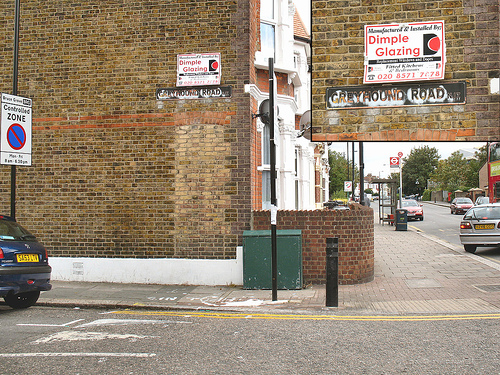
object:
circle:
[7, 124, 26, 151]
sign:
[176, 52, 223, 87]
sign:
[362, 21, 443, 83]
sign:
[325, 82, 456, 110]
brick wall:
[248, 207, 377, 289]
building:
[1, 1, 326, 286]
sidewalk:
[35, 224, 498, 316]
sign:
[0, 91, 33, 166]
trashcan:
[396, 208, 408, 231]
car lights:
[460, 221, 473, 229]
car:
[459, 205, 498, 255]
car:
[394, 198, 424, 221]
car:
[450, 197, 473, 215]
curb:
[48, 295, 325, 325]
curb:
[408, 222, 498, 277]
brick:
[76, 67, 221, 220]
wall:
[0, 0, 250, 260]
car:
[0, 217, 52, 315]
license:
[473, 224, 495, 230]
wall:
[246, 222, 372, 286]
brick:
[188, 25, 223, 40]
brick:
[103, 82, 130, 92]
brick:
[76, 155, 95, 162]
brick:
[153, 170, 175, 178]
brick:
[196, 206, 213, 214]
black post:
[326, 238, 338, 307]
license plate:
[17, 252, 40, 262]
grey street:
[0, 299, 499, 374]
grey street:
[371, 192, 476, 245]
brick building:
[0, 5, 372, 285]